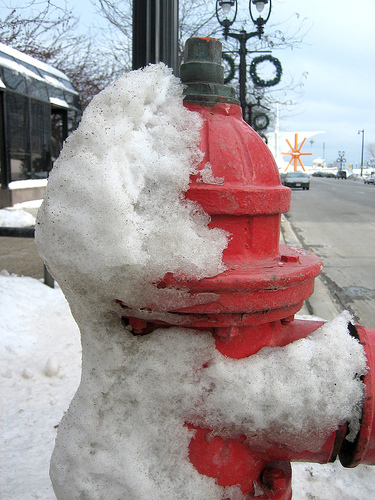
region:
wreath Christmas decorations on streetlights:
[214, 0, 281, 148]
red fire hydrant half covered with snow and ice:
[34, 35, 370, 497]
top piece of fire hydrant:
[178, 34, 233, 99]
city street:
[266, 170, 372, 326]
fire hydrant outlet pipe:
[289, 317, 372, 470]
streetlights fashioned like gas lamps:
[217, 2, 271, 36]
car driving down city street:
[285, 170, 287, 189]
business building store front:
[1, 42, 76, 205]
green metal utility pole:
[131, 0, 179, 74]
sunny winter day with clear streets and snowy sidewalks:
[0, 0, 373, 499]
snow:
[75, 134, 158, 242]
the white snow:
[109, 384, 169, 468]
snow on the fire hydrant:
[81, 362, 188, 458]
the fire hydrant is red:
[237, 241, 302, 319]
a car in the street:
[287, 169, 314, 188]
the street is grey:
[312, 205, 355, 240]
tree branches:
[69, 48, 108, 87]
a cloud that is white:
[321, 56, 359, 102]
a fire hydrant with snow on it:
[73, 62, 330, 484]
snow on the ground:
[4, 286, 75, 494]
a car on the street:
[278, 161, 325, 195]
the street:
[294, 186, 373, 253]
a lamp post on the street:
[355, 121, 374, 183]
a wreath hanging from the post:
[254, 58, 289, 93]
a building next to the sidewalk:
[8, 55, 60, 154]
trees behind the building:
[12, 13, 145, 63]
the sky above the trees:
[15, 10, 139, 48]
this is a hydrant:
[181, 94, 301, 495]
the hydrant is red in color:
[224, 140, 269, 198]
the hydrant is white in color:
[34, 70, 197, 298]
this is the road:
[319, 180, 362, 238]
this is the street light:
[221, 2, 276, 26]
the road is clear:
[324, 185, 362, 229]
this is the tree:
[37, 5, 122, 51]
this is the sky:
[322, 23, 371, 83]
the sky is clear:
[332, 28, 365, 84]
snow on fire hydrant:
[33, 63, 366, 499]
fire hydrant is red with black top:
[104, 37, 374, 499]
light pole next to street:
[356, 127, 366, 177]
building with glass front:
[0, 42, 84, 213]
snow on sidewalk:
[1, 273, 373, 496]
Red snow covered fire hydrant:
[37, 38, 372, 494]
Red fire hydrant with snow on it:
[32, 35, 372, 496]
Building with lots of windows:
[0, 40, 81, 205]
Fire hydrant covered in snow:
[55, 38, 373, 497]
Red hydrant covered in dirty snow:
[38, 36, 374, 497]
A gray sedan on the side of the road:
[280, 169, 313, 189]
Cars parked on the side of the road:
[310, 167, 374, 183]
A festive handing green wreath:
[250, 53, 282, 86]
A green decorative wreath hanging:
[249, 54, 281, 86]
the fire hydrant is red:
[34, 35, 374, 499]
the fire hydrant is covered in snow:
[35, 37, 374, 496]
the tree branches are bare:
[0, 1, 315, 137]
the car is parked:
[283, 170, 309, 190]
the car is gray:
[284, 170, 310, 190]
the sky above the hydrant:
[0, 0, 374, 498]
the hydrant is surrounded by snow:
[0, 36, 372, 498]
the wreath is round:
[250, 54, 282, 87]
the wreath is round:
[253, 111, 270, 130]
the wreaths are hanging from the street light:
[214, 0, 283, 119]